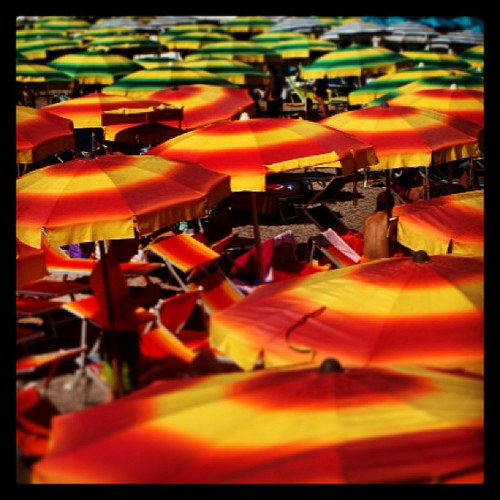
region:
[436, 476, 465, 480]
Dog in the back next to a green tree.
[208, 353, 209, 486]
Dog in the back next to a green tree.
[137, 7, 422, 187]
many umbrellas are open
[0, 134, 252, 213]
the umbrella is red and yellow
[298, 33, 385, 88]
the umbrella is green and yellow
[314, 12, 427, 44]
the umbrellas are striped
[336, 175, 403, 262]
the person is standing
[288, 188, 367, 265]
the chairs are empty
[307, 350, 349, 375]
the tip of the umbrella is black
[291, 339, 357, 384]
the tip of the umbrella is round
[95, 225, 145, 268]
the man is wearing glasses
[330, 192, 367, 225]
the sand has foot prints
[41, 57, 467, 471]
Umbrellas on the beach.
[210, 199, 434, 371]
Red and yellow stripes.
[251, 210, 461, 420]
Red and yellow umbrella.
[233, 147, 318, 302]
pole on the umbrella.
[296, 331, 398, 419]
Top of the umbrella.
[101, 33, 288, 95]
Green and yellow umbrella.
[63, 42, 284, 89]
Green and yellow stripes.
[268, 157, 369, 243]
Chair on the sand.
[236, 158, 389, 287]
Sand on the ground.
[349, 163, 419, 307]
Person by the umbrellas.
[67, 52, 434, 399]
Umbrellas on the beach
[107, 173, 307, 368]
Umbrellas on the beach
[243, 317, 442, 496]
Umbrellas on the beach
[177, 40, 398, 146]
Umbrellas on the beach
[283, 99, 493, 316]
Umbrellas on the beach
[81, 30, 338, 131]
Umbrellas on the beach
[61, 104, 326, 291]
Umbrellas on the beach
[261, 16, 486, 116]
Umbrellas on the beach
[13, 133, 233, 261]
orange and yellow unbrella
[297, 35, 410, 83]
green and yellow umbrella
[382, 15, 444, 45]
blue and white umbrella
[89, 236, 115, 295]
pole of a umbrella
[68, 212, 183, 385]
man under a umbrella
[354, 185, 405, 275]
back of man under a umbrella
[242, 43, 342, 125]
two persons standing in sand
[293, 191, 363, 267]
lawn seat in sand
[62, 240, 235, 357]
several folding seats in sand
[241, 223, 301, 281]
pink and white towel on chair